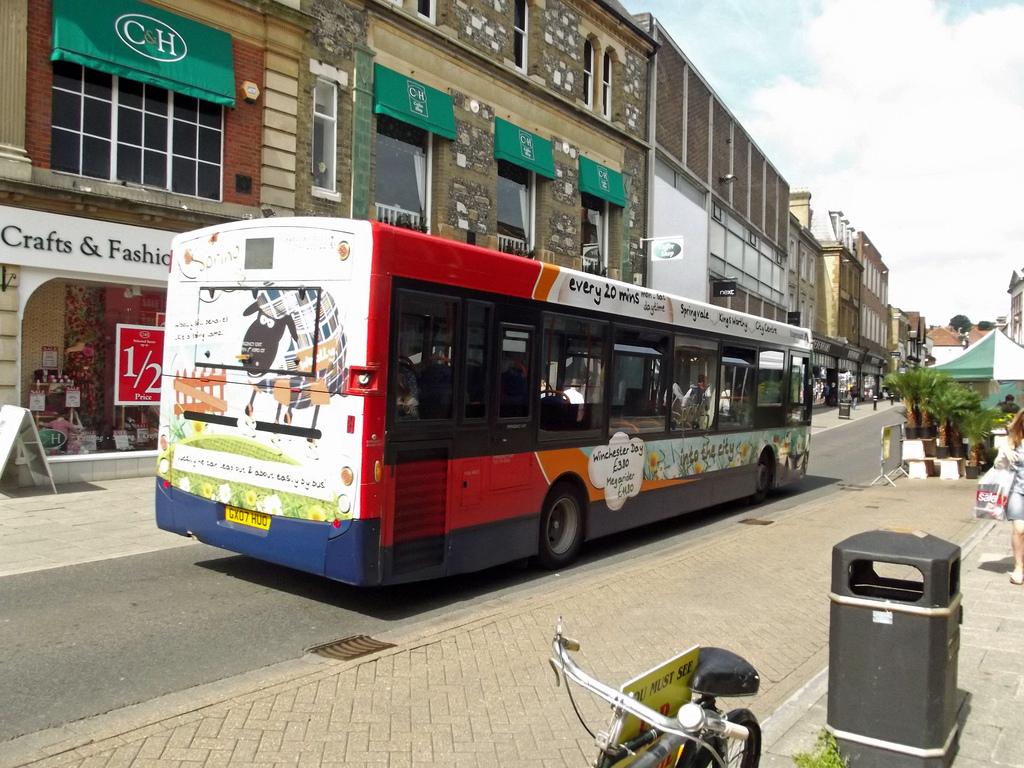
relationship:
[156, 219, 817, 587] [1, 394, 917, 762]
bus on street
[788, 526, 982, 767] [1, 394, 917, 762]
trash can on street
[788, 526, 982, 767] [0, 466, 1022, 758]
trash can on sidewalk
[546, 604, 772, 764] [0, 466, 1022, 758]
bicycle on sidewalk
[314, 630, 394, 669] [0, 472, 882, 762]
grate against curb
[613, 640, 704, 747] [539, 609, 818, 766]
sign against bike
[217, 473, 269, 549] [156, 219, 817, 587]
license plate on bus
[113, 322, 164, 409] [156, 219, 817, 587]
poster behind bus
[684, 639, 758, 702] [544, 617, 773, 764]
seat on bike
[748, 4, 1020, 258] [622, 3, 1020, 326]
clouds in sky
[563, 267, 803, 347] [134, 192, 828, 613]
lettering on bus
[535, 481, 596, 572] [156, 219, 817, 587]
tire on bus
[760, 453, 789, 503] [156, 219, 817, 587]
tire on bus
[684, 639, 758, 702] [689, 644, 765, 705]
seat on bicycle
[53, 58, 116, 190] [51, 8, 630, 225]
window below greencanopies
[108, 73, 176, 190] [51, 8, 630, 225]
window below greencanopies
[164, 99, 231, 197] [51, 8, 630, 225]
window below greencanopies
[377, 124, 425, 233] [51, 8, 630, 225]
window below greencanopies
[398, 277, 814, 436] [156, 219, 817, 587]
windows on bus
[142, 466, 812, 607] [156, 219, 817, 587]
stripe on bus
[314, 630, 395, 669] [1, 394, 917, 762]
grate on street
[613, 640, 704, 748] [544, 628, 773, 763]
sign leaning against bicycle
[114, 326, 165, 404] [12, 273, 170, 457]
poster on window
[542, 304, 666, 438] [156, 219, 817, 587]
stripe on bus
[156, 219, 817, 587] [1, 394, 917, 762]
bus stopped on street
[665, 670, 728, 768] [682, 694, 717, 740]
circle on bike